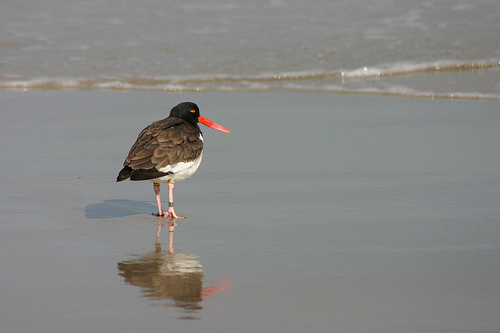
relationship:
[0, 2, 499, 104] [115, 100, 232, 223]
water with bird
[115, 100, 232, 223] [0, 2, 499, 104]
bird in water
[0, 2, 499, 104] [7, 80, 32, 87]
water has part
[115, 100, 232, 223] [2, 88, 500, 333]
bird standing on beach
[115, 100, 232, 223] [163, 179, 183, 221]
bird has leg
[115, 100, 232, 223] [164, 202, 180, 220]
bird has foot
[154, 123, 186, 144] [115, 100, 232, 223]
feather on top of bird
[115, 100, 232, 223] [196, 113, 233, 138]
bird has beak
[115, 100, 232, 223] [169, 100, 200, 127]
bird has head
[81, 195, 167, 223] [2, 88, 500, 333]
shadow on top of beach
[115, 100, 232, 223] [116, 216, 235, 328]
bird has reflection